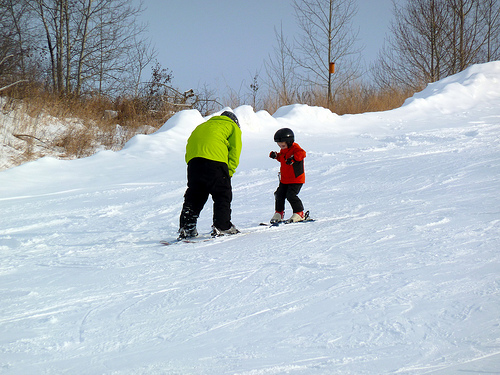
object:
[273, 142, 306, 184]
jacket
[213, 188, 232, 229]
leg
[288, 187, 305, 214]
leg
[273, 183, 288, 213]
leg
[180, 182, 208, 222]
leg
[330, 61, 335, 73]
can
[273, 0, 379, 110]
tree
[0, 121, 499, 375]
ground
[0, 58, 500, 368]
hillside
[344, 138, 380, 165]
snow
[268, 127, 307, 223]
child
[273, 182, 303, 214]
pants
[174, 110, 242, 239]
adult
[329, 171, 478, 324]
snow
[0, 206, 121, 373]
snow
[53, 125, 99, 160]
bush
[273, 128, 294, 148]
helmet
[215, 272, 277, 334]
snow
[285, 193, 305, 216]
personleg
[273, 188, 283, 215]
personleg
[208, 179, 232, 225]
personleg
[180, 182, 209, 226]
personleg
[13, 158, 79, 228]
snow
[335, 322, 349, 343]
snow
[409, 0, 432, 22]
leaves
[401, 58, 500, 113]
pile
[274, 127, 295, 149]
head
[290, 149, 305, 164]
arm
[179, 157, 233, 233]
pants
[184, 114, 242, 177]
jacket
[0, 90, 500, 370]
tracks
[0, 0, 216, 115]
trees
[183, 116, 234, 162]
back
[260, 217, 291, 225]
ski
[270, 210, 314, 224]
ski